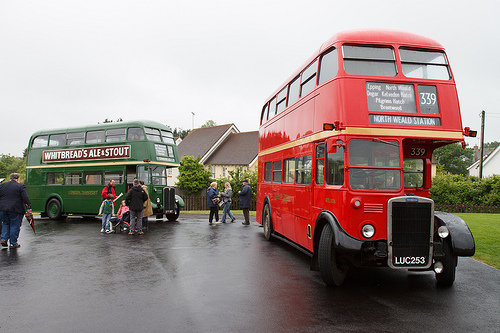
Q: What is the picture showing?
A: It is showing a pavement.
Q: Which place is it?
A: It is a pavement.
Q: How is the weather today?
A: It is overcast.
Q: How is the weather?
A: It is overcast.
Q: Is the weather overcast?
A: Yes, it is overcast.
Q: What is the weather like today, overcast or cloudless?
A: It is overcast.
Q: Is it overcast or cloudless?
A: It is overcast.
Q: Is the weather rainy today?
A: No, it is overcast.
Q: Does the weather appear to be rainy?
A: No, it is overcast.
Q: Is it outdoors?
A: Yes, it is outdoors.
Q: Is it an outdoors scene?
A: Yes, it is outdoors.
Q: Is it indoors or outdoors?
A: It is outdoors.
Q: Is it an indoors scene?
A: No, it is outdoors.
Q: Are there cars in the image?
A: No, there are no cars.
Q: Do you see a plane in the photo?
A: No, there are no airplanes.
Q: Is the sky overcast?
A: Yes, the sky is overcast.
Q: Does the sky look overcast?
A: Yes, the sky is overcast.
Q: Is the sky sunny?
A: No, the sky is overcast.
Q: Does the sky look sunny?
A: No, the sky is overcast.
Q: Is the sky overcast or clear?
A: The sky is overcast.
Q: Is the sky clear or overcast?
A: The sky is overcast.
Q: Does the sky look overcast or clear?
A: The sky is overcast.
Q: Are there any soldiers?
A: No, there are no soldiers.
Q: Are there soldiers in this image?
A: No, there are no soldiers.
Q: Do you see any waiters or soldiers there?
A: No, there are no soldiers or waiters.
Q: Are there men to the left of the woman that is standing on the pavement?
A: Yes, there is a man to the left of the woman.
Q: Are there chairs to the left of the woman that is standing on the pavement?
A: No, there is a man to the left of the woman.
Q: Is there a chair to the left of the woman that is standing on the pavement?
A: No, there is a man to the left of the woman.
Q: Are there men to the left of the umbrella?
A: No, the man is to the right of the umbrella.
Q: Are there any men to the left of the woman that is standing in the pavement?
A: Yes, there is a man to the left of the woman.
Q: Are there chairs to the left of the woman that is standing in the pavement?
A: No, there is a man to the left of the woman.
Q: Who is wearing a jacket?
A: The man is wearing a jacket.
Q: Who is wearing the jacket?
A: The man is wearing a jacket.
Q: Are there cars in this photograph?
A: No, there are no cars.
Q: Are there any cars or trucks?
A: No, there are no cars or trucks.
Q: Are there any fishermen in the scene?
A: No, there are no fishermen.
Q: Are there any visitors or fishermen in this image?
A: No, there are no fishermen or visitors.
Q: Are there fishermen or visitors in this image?
A: No, there are no fishermen or visitors.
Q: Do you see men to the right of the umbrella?
A: Yes, there is a man to the right of the umbrella.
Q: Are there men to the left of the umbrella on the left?
A: No, the man is to the right of the umbrella.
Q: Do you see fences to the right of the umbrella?
A: No, there is a man to the right of the umbrella.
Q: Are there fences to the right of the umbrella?
A: No, there is a man to the right of the umbrella.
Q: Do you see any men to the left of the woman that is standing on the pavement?
A: Yes, there is a man to the left of the woman.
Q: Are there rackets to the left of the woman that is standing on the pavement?
A: No, there is a man to the left of the woman.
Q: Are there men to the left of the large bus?
A: Yes, there is a man to the left of the bus.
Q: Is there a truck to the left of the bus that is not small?
A: No, there is a man to the left of the bus.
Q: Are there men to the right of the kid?
A: Yes, there is a man to the right of the kid.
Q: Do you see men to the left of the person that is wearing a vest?
A: No, the man is to the right of the child.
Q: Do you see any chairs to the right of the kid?
A: No, there is a man to the right of the kid.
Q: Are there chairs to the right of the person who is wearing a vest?
A: No, there is a man to the right of the kid.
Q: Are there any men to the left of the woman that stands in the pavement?
A: Yes, there is a man to the left of the woman.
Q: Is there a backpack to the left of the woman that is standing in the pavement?
A: No, there is a man to the left of the woman.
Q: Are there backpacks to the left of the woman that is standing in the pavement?
A: No, there is a man to the left of the woman.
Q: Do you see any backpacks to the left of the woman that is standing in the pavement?
A: No, there is a man to the left of the woman.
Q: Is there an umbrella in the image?
A: Yes, there is an umbrella.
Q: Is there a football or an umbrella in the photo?
A: Yes, there is an umbrella.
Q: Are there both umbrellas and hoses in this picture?
A: No, there is an umbrella but no hoses.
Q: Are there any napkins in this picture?
A: No, there are no napkins.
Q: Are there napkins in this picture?
A: No, there are no napkins.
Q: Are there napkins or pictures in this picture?
A: No, there are no napkins or pictures.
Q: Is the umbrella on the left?
A: Yes, the umbrella is on the left of the image.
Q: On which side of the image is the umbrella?
A: The umbrella is on the left of the image.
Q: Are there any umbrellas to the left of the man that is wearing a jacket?
A: Yes, there is an umbrella to the left of the man.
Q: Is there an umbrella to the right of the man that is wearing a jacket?
A: No, the umbrella is to the left of the man.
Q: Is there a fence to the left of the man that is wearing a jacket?
A: No, there is an umbrella to the left of the man.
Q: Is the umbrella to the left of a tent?
A: No, the umbrella is to the left of a man.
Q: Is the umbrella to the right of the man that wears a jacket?
A: No, the umbrella is to the left of the man.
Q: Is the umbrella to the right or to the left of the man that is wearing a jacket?
A: The umbrella is to the left of the man.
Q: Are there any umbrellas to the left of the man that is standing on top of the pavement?
A: Yes, there is an umbrella to the left of the man.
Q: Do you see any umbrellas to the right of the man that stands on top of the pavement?
A: No, the umbrella is to the left of the man.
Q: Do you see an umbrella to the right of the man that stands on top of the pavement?
A: No, the umbrella is to the left of the man.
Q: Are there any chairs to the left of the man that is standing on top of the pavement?
A: No, there is an umbrella to the left of the man.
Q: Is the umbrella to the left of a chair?
A: No, the umbrella is to the left of the man.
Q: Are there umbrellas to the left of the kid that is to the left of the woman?
A: Yes, there is an umbrella to the left of the child.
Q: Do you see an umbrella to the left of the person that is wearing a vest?
A: Yes, there is an umbrella to the left of the child.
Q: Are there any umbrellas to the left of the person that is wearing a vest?
A: Yes, there is an umbrella to the left of the child.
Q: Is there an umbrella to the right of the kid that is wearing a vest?
A: No, the umbrella is to the left of the kid.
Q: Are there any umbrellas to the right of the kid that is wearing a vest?
A: No, the umbrella is to the left of the kid.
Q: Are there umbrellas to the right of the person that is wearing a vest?
A: No, the umbrella is to the left of the kid.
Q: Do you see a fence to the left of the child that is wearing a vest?
A: No, there is an umbrella to the left of the child.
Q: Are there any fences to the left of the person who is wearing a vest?
A: No, there is an umbrella to the left of the child.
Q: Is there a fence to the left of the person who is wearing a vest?
A: No, there is an umbrella to the left of the child.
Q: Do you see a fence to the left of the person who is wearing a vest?
A: No, there is an umbrella to the left of the child.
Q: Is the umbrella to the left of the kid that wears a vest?
A: Yes, the umbrella is to the left of the child.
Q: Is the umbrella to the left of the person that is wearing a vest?
A: Yes, the umbrella is to the left of the child.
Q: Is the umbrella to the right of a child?
A: No, the umbrella is to the left of a child.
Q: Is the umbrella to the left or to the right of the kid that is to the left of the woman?
A: The umbrella is to the left of the child.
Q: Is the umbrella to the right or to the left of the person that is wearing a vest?
A: The umbrella is to the left of the child.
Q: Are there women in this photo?
A: Yes, there is a woman.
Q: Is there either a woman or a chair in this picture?
A: Yes, there is a woman.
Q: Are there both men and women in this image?
A: Yes, there are both a woman and a man.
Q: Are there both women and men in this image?
A: Yes, there are both a woman and a man.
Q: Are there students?
A: No, there are no students.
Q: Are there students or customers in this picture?
A: No, there are no students or customers.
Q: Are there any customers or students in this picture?
A: No, there are no students or customers.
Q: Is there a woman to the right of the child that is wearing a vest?
A: Yes, there is a woman to the right of the child.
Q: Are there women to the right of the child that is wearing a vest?
A: Yes, there is a woman to the right of the child.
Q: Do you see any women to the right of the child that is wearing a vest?
A: Yes, there is a woman to the right of the child.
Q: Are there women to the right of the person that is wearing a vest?
A: Yes, there is a woman to the right of the child.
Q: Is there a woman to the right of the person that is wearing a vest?
A: Yes, there is a woman to the right of the child.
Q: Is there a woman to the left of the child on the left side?
A: No, the woman is to the right of the child.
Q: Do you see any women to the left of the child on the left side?
A: No, the woman is to the right of the child.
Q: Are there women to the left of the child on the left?
A: No, the woman is to the right of the child.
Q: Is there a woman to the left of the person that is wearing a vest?
A: No, the woman is to the right of the child.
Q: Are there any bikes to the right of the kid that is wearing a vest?
A: No, there is a woman to the right of the child.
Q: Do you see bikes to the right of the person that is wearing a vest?
A: No, there is a woman to the right of the child.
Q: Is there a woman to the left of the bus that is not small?
A: Yes, there is a woman to the left of the bus.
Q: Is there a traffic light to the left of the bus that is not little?
A: No, there is a woman to the left of the bus.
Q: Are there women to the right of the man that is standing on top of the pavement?
A: Yes, there is a woman to the right of the man.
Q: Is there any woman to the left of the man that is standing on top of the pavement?
A: No, the woman is to the right of the man.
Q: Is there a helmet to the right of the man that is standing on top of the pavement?
A: No, there is a woman to the right of the man.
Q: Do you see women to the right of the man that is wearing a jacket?
A: Yes, there is a woman to the right of the man.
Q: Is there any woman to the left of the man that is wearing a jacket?
A: No, the woman is to the right of the man.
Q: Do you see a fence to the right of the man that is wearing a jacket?
A: No, there is a woman to the right of the man.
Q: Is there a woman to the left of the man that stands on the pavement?
A: Yes, there is a woman to the left of the man.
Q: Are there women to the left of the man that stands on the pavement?
A: Yes, there is a woman to the left of the man.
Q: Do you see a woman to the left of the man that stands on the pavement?
A: Yes, there is a woman to the left of the man.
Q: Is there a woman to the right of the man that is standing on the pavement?
A: No, the woman is to the left of the man.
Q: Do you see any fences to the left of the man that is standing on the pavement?
A: No, there is a woman to the left of the man.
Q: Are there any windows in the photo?
A: Yes, there is a window.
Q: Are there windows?
A: Yes, there is a window.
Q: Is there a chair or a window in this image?
A: Yes, there is a window.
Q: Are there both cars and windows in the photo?
A: No, there is a window but no cars.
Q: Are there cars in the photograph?
A: No, there are no cars.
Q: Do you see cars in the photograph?
A: No, there are no cars.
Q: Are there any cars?
A: No, there are no cars.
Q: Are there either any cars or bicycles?
A: No, there are no cars or bicycles.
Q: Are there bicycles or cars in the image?
A: No, there are no cars or bicycles.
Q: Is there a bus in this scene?
A: Yes, there is a bus.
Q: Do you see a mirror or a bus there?
A: Yes, there is a bus.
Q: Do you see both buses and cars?
A: No, there is a bus but no cars.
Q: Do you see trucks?
A: No, there are no trucks.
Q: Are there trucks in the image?
A: No, there are no trucks.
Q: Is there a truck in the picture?
A: No, there are no trucks.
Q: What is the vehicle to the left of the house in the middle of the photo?
A: The vehicle is a bus.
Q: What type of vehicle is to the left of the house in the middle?
A: The vehicle is a bus.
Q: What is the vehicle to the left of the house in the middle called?
A: The vehicle is a bus.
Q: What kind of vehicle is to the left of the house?
A: The vehicle is a bus.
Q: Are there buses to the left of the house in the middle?
A: Yes, there is a bus to the left of the house.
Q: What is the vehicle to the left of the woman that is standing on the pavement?
A: The vehicle is a bus.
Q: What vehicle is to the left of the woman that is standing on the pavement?
A: The vehicle is a bus.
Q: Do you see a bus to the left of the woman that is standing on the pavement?
A: Yes, there is a bus to the left of the woman.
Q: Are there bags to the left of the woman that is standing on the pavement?
A: No, there is a bus to the left of the woman.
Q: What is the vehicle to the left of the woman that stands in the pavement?
A: The vehicle is a bus.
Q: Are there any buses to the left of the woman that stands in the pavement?
A: Yes, there is a bus to the left of the woman.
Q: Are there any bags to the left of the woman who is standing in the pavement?
A: No, there is a bus to the left of the woman.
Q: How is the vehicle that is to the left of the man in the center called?
A: The vehicle is a bus.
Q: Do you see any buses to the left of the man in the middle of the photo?
A: Yes, there is a bus to the left of the man.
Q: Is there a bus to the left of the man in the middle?
A: Yes, there is a bus to the left of the man.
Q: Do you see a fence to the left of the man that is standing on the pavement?
A: No, there is a bus to the left of the man.